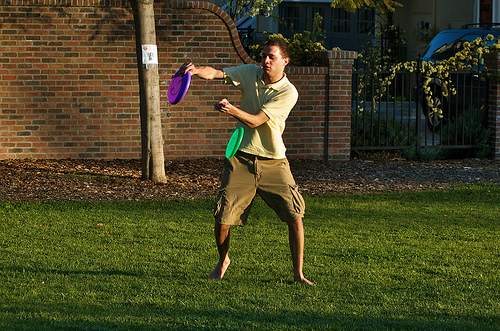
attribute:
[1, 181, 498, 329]
grass — sunny, short, green, lush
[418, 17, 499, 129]
suv — black, parked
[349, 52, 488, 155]
gate — metal, black, small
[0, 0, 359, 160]
brick wall — multicolored, red gray, brown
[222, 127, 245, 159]
frisbee — green, small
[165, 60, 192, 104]
frisbee — purple, big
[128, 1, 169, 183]
tree trunk — large, brown, gray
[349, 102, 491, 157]
shrubs — green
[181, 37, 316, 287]
man — young, barefoot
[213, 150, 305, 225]
shorts — tan, khaki, cargo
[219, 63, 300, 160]
shirt — pale yellow, tan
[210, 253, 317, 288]
feet — bare